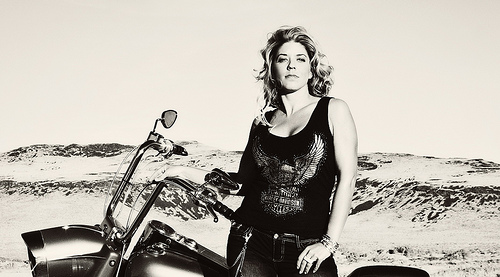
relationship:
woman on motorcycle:
[225, 22, 356, 273] [7, 104, 441, 275]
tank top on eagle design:
[235, 94, 334, 237] [252, 132, 330, 216]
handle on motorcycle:
[144, 134, 189, 152] [20, 108, 430, 277]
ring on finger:
[303, 257, 310, 265] [295, 247, 309, 269]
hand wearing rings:
[291, 235, 346, 275] [300, 253, 317, 265]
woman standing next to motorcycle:
[233, 24, 338, 275] [22, 111, 419, 275]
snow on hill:
[22, 150, 220, 218] [9, 142, 496, 227]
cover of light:
[24, 221, 107, 274] [19, 231, 46, 270]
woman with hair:
[225, 22, 356, 273] [260, 17, 332, 94]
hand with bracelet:
[296, 242, 334, 273] [321, 234, 341, 254]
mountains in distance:
[358, 145, 498, 267] [7, 115, 485, 199]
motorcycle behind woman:
[45, 133, 232, 272] [176, 15, 416, 259]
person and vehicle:
[225, 23, 360, 275] [18, 107, 430, 274]